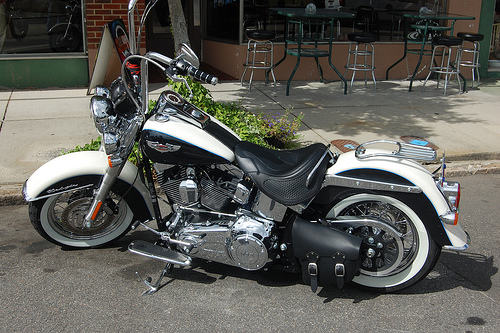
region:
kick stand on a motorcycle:
[122, 251, 174, 317]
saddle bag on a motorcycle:
[274, 213, 373, 299]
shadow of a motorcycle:
[409, 245, 492, 302]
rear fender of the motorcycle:
[319, 139, 481, 266]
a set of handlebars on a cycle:
[100, 0, 225, 130]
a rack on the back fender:
[341, 133, 453, 175]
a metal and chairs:
[238, 5, 388, 107]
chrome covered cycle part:
[164, 213, 274, 276]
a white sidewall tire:
[309, 186, 439, 295]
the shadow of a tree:
[221, 66, 494, 138]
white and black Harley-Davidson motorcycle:
[8, 41, 473, 331]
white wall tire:
[316, 176, 451, 296]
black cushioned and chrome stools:
[221, 23, 482, 93]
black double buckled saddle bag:
[286, 215, 368, 308]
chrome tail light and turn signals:
[430, 171, 469, 224]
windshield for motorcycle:
[89, 10, 139, 101]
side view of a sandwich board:
[86, 13, 141, 103]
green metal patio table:
[271, 1, 354, 93]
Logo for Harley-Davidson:
[143, 130, 182, 167]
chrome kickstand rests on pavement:
[134, 256, 191, 307]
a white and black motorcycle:
[13, 62, 477, 315]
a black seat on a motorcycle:
[236, 125, 343, 207]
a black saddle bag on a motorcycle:
[267, 218, 387, 298]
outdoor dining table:
[391, 5, 476, 100]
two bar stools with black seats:
[434, 25, 486, 98]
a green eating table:
[275, 7, 368, 91]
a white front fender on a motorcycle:
[28, 140, 137, 247]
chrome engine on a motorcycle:
[137, 173, 286, 288]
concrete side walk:
[327, 94, 476, 159]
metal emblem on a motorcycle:
[141, 132, 191, 159]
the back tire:
[311, 193, 436, 297]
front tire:
[25, 186, 143, 251]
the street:
[37, 278, 123, 330]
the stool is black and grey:
[430, 37, 466, 97]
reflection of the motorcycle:
[41, 17, 81, 52]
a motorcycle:
[35, 62, 470, 308]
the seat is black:
[237, 142, 325, 197]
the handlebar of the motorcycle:
[150, 45, 220, 90]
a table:
[268, 6, 348, 97]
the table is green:
[399, 11, 475, 39]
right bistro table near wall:
[395, 7, 488, 99]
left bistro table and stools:
[238, 9, 382, 104]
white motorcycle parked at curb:
[20, 18, 472, 330]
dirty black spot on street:
[447, 303, 495, 331]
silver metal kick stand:
[137, 255, 184, 305]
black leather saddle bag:
[273, 208, 369, 303]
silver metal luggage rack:
[350, 132, 444, 169]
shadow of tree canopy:
[239, 70, 476, 140]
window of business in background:
[230, 3, 459, 53]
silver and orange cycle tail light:
[432, 167, 467, 237]